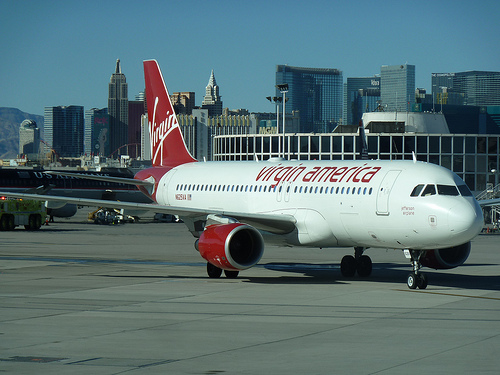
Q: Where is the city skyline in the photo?
A: Behind the airplane.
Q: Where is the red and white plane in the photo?
A: On the runway.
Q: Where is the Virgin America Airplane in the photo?
A: The red and white plane.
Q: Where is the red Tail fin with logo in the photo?
A: Back of plane.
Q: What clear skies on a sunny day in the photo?
A: Blue clear skies.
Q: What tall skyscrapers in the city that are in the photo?
A: The tall grey skyscrapers.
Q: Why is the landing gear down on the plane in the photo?
A: Plane has landing.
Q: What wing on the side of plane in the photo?
A: Wing on the left.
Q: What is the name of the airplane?
A: Virgin America.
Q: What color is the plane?
A: White.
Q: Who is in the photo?
A: No one.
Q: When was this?
A: Daytime.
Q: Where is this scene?
A: Air[port.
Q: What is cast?
A: Shadow.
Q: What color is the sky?
A: Blue.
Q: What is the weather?
A: Sunny.